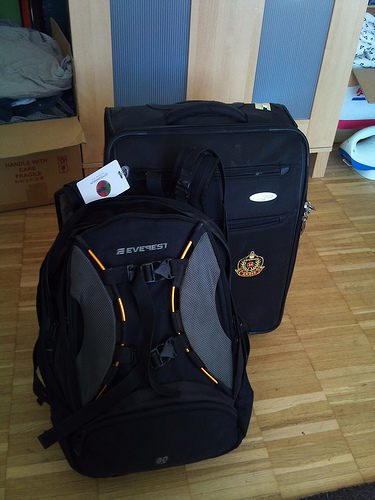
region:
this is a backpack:
[37, 136, 271, 478]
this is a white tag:
[60, 144, 162, 220]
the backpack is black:
[26, 183, 256, 498]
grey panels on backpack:
[69, 226, 254, 408]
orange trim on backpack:
[69, 226, 242, 423]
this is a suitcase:
[100, 85, 331, 329]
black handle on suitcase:
[158, 88, 264, 135]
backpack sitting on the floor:
[41, 183, 292, 498]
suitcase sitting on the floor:
[79, 83, 331, 361]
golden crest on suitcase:
[231, 243, 268, 283]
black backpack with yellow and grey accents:
[14, 161, 264, 482]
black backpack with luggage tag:
[25, 151, 267, 472]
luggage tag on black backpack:
[71, 155, 142, 212]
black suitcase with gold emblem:
[99, 101, 309, 347]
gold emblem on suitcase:
[231, 246, 276, 288]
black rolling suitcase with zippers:
[101, 88, 314, 346]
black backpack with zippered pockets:
[27, 157, 260, 478]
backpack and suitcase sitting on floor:
[31, 75, 324, 481]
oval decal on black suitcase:
[245, 189, 280, 208]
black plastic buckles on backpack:
[123, 254, 183, 373]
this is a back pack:
[28, 184, 247, 476]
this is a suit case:
[91, 99, 308, 341]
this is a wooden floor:
[268, 421, 330, 494]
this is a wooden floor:
[288, 279, 343, 347]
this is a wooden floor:
[260, 399, 322, 477]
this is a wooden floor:
[12, 440, 42, 476]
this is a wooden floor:
[306, 290, 354, 335]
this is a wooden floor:
[290, 352, 336, 412]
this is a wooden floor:
[307, 336, 348, 393]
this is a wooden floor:
[9, 220, 26, 256]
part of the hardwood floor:
[305, 375, 370, 440]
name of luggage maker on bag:
[114, 242, 169, 254]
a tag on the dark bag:
[73, 166, 128, 198]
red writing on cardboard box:
[1, 143, 51, 184]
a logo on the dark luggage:
[233, 247, 266, 278]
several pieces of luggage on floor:
[23, 93, 303, 489]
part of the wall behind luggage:
[282, 6, 306, 89]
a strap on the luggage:
[105, 262, 180, 280]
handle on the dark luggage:
[167, 103, 245, 124]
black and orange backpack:
[71, 222, 248, 456]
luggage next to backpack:
[100, 93, 292, 331]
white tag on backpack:
[61, 160, 140, 211]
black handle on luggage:
[156, 89, 249, 126]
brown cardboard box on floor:
[0, 110, 101, 208]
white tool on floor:
[339, 127, 371, 188]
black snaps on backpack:
[121, 240, 181, 363]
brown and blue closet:
[96, 1, 345, 185]